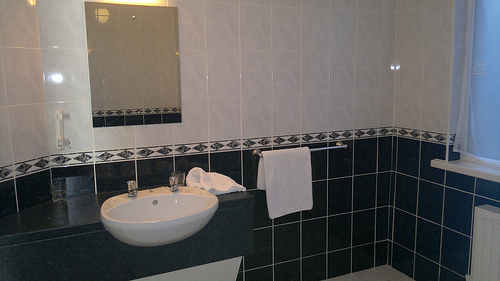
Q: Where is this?
A: This is at the bathroom.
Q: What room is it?
A: It is a bathroom.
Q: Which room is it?
A: It is a bathroom.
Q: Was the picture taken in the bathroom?
A: Yes, it was taken in the bathroom.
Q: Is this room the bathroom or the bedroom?
A: It is the bathroom.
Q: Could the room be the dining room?
A: No, it is the bathroom.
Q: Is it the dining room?
A: No, it is the bathroom.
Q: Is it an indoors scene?
A: Yes, it is indoors.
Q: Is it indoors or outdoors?
A: It is indoors.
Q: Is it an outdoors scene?
A: No, it is indoors.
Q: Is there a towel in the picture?
A: Yes, there is a towel.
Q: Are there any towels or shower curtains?
A: Yes, there is a towel.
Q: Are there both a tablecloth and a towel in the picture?
A: No, there is a towel but no tablecloths.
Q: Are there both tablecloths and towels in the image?
A: No, there is a towel but no tablecloths.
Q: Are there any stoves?
A: No, there are no stoves.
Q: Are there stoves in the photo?
A: No, there are no stoves.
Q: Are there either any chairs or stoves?
A: No, there are no stoves or chairs.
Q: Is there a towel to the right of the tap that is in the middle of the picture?
A: Yes, there is a towel to the right of the tap.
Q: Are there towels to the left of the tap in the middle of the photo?
A: No, the towel is to the right of the tap.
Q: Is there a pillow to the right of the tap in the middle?
A: No, there is a towel to the right of the faucet.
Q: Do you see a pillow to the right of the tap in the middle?
A: No, there is a towel to the right of the faucet.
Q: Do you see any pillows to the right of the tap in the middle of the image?
A: No, there is a towel to the right of the faucet.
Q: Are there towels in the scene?
A: Yes, there is a towel.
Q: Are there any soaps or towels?
A: Yes, there is a towel.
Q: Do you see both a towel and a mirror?
A: Yes, there are both a towel and a mirror.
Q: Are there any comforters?
A: No, there are no comforters.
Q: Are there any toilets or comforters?
A: No, there are no comforters or toilets.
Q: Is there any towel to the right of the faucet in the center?
A: Yes, there is a towel to the right of the faucet.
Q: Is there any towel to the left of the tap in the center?
A: No, the towel is to the right of the tap.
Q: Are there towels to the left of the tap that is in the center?
A: No, the towel is to the right of the tap.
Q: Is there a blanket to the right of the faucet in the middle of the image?
A: No, there is a towel to the right of the tap.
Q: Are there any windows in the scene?
A: Yes, there is a window.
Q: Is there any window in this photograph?
A: Yes, there is a window.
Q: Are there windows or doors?
A: Yes, there is a window.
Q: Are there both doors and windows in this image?
A: No, there is a window but no doors.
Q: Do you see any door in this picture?
A: No, there are no doors.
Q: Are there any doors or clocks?
A: No, there are no doors or clocks.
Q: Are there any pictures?
A: No, there are no pictures.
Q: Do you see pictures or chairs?
A: No, there are no pictures or chairs.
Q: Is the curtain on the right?
A: Yes, the curtain is on the right of the image.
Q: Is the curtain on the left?
A: No, the curtain is on the right of the image.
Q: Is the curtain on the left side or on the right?
A: The curtain is on the right of the image.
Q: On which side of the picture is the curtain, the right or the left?
A: The curtain is on the right of the image.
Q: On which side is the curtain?
A: The curtain is on the right of the image.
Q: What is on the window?
A: The curtain is on the window.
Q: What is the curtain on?
A: The curtain is on the window.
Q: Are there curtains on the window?
A: Yes, there is a curtain on the window.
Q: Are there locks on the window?
A: No, there is a curtain on the window.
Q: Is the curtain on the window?
A: Yes, the curtain is on the window.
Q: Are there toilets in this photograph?
A: No, there are no toilets.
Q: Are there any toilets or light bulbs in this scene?
A: No, there are no toilets or light bulbs.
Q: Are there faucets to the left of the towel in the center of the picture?
A: Yes, there is a faucet to the left of the towel.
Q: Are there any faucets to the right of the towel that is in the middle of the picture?
A: No, the faucet is to the left of the towel.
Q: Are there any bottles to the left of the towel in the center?
A: No, there is a faucet to the left of the towel.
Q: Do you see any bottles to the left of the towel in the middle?
A: No, there is a faucet to the left of the towel.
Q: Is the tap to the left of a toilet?
A: No, the tap is to the left of a towel.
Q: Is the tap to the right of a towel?
A: No, the tap is to the left of a towel.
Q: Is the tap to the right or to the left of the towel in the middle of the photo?
A: The tap is to the left of the towel.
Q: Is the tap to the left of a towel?
A: Yes, the tap is to the left of a towel.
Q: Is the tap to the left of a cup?
A: No, the tap is to the left of a towel.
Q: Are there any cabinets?
A: No, there are no cabinets.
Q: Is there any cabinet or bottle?
A: No, there are no cabinets or bottles.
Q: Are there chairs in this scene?
A: No, there are no chairs.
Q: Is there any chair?
A: No, there are no chairs.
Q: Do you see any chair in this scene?
A: No, there are no chairs.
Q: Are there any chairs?
A: No, there are no chairs.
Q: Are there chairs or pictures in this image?
A: No, there are no chairs or pictures.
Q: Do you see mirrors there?
A: Yes, there is a mirror.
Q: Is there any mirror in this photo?
A: Yes, there is a mirror.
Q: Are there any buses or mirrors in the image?
A: Yes, there is a mirror.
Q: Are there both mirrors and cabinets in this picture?
A: No, there is a mirror but no cabinets.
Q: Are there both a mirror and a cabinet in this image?
A: No, there is a mirror but no cabinets.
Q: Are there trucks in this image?
A: No, there are no trucks.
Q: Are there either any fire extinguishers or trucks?
A: No, there are no trucks or fire extinguishers.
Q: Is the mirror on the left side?
A: Yes, the mirror is on the left of the image.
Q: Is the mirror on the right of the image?
A: No, the mirror is on the left of the image.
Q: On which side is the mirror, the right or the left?
A: The mirror is on the left of the image.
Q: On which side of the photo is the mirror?
A: The mirror is on the left of the image.